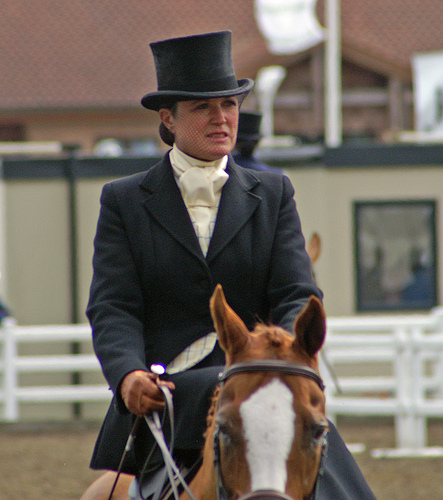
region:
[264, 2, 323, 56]
a white flag behind the fence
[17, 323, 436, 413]
a white fence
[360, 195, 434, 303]
a picture on the wall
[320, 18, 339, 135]
a white pole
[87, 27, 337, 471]
a lady riding a horse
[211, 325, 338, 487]
a brown and white horse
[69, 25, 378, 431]
a lady wearing a black top hat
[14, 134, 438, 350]
a building behind the lady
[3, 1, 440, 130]
a roof of a building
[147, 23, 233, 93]
Person wearing black hat.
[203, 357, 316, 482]
Dark straps on horse's face.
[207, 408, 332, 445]
Horse has large dark eyes.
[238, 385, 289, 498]
White markings on horse's face.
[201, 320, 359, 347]
Horse has brown ears.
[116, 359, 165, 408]
Person wearing brown gloves.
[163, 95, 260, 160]
Black netting over person's face.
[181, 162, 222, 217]
Cream colored tie around person's neck.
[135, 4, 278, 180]
the head of a woman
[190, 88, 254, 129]
the eye of a woman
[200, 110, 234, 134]
the nose of a woman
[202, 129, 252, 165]
the chin of a woman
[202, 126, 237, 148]
the lips of a woman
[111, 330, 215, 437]
the hand of a woman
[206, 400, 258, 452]
the eye of a horse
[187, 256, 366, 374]
the ear of a horse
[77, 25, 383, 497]
Woman riding a horse.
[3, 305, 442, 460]
White fence in the background.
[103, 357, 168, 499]
Riding whip in the hand.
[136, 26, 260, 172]
Top hat on the woman.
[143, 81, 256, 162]
Black netting over the face.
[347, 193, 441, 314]
Picture on the wall.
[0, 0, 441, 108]
Rust colored roof on the building.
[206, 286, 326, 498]
White coloring on the horse.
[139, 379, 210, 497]
Black reins attached to the horse.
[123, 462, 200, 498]
Saddle on the horse.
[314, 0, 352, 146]
a small thin white pole.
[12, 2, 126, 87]
a dark pink wall paper.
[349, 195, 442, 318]
a black framed blurry picture.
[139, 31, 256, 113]
a woman is wearing a black hat.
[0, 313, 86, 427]
a white fence.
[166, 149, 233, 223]
a woman is wearing a beige bow tie.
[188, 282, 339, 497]
a brown and white horse.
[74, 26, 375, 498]
a woman is going horse back riding.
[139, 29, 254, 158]
hat with veil atop woman's head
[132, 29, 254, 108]
a black top hat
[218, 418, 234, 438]
eye of the horse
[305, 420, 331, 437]
left eye of the horse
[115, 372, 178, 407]
brown glove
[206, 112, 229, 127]
nose of the woman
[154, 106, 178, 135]
ear of the woman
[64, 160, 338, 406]
the jacket is black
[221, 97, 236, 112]
left eye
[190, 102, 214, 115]
right eye of the woman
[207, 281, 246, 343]
horse ear